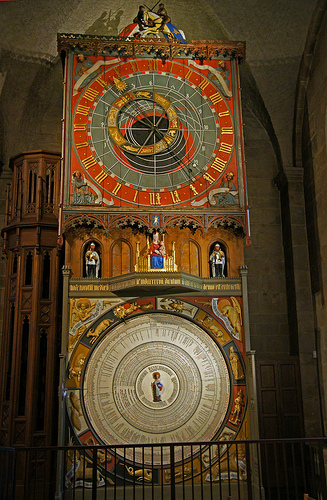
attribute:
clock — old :
[44, 37, 265, 226]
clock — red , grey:
[65, 173, 110, 210]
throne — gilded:
[135, 232, 180, 273]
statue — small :
[206, 241, 227, 275]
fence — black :
[2, 435, 325, 498]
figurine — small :
[84, 241, 99, 277]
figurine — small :
[147, 231, 166, 265]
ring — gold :
[107, 75, 181, 164]